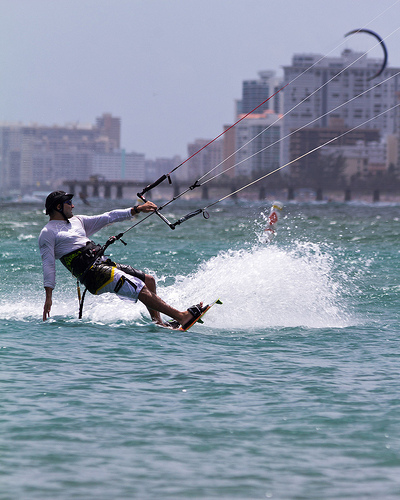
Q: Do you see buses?
A: No, there are no buses.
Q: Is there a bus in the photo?
A: No, there are no buses.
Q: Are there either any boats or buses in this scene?
A: No, there are no buses or boats.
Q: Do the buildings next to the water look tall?
A: Yes, the buildings are tall.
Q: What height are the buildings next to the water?
A: The buildings are tall.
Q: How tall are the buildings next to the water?
A: The buildings are tall.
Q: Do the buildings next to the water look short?
A: No, the buildings are tall.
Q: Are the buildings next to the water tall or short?
A: The buildings are tall.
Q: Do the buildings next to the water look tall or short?
A: The buildings are tall.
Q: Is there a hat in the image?
A: Yes, there is a hat.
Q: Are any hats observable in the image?
A: Yes, there is a hat.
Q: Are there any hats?
A: Yes, there is a hat.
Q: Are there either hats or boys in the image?
A: Yes, there is a hat.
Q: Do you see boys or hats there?
A: Yes, there is a hat.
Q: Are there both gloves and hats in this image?
A: No, there is a hat but no gloves.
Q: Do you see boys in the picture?
A: No, there are no boys.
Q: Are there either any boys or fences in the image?
A: No, there are no boys or fences.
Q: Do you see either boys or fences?
A: No, there are no boys or fences.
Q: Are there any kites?
A: Yes, there is a kite.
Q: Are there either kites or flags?
A: Yes, there is a kite.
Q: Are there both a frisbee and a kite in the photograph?
A: No, there is a kite but no frisbees.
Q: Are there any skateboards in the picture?
A: No, there are no skateboards.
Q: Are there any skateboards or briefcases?
A: No, there are no skateboards or briefcases.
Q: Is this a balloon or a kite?
A: This is a kite.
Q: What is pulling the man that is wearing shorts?
A: The kite is pulling the man.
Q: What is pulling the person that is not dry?
A: The kite is pulling the man.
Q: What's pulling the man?
A: The kite is pulling the man.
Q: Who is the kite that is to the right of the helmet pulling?
A: The kite is pulling the man.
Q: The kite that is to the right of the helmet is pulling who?
A: The kite is pulling the man.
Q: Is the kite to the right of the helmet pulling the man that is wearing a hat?
A: Yes, the kite is pulling the man.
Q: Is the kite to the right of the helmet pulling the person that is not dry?
A: Yes, the kite is pulling the man.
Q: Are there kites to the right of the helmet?
A: Yes, there is a kite to the right of the helmet.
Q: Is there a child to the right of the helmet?
A: No, there is a kite to the right of the helmet.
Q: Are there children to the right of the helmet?
A: No, there is a kite to the right of the helmet.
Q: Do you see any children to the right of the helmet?
A: No, there is a kite to the right of the helmet.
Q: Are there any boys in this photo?
A: No, there are no boys.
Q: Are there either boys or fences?
A: No, there are no boys or fences.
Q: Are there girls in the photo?
A: No, there are no girls.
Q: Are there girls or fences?
A: No, there are no girls or fences.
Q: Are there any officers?
A: No, there are no officers.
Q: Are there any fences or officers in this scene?
A: No, there are no officers or fences.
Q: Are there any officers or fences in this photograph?
A: No, there are no officers or fences.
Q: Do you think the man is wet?
A: Yes, the man is wet.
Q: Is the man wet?
A: Yes, the man is wet.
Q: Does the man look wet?
A: Yes, the man is wet.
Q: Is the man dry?
A: No, the man is wet.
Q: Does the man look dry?
A: No, the man is wet.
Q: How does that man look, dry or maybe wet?
A: The man is wet.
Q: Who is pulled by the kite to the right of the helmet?
A: The man is pulled by the kite.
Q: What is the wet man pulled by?
A: The man is pulled by the kite.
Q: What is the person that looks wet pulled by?
A: The man is pulled by the kite.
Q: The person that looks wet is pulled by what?
A: The man is pulled by the kite.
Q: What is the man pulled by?
A: The man is pulled by the kite.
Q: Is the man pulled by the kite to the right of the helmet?
A: Yes, the man is pulled by the kite.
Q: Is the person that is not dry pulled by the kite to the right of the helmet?
A: Yes, the man is pulled by the kite.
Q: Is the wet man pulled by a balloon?
A: No, the man is pulled by the kite.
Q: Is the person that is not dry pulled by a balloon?
A: No, the man is pulled by the kite.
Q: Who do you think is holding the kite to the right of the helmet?
A: The man is holding the kite.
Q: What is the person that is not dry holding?
A: The man is holding the kite.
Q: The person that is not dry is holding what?
A: The man is holding the kite.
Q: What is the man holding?
A: The man is holding the kite.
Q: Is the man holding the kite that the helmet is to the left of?
A: Yes, the man is holding the kite.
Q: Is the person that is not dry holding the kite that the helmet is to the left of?
A: Yes, the man is holding the kite.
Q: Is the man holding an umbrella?
A: No, the man is holding the kite.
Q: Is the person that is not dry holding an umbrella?
A: No, the man is holding the kite.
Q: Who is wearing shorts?
A: The man is wearing shorts.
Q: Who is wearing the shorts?
A: The man is wearing shorts.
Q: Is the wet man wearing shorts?
A: Yes, the man is wearing shorts.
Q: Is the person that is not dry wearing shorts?
A: Yes, the man is wearing shorts.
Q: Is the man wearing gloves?
A: No, the man is wearing shorts.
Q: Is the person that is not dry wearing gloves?
A: No, the man is wearing shorts.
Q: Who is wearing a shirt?
A: The man is wearing a shirt.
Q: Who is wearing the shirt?
A: The man is wearing a shirt.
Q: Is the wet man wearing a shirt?
A: Yes, the man is wearing a shirt.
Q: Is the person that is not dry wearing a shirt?
A: Yes, the man is wearing a shirt.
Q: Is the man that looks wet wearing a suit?
A: No, the man is wearing a shirt.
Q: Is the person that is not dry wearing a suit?
A: No, the man is wearing a shirt.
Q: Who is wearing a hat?
A: The man is wearing a hat.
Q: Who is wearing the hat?
A: The man is wearing a hat.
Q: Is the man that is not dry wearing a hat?
A: Yes, the man is wearing a hat.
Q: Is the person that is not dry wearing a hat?
A: Yes, the man is wearing a hat.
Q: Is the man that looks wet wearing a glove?
A: No, the man is wearing a hat.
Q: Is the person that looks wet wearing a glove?
A: No, the man is wearing a hat.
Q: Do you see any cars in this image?
A: No, there are no cars.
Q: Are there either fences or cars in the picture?
A: No, there are no cars or fences.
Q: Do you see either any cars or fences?
A: No, there are no cars or fences.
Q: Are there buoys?
A: Yes, there is a buoy.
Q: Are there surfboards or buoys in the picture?
A: Yes, there is a buoy.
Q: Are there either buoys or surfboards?
A: Yes, there is a buoy.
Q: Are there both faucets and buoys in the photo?
A: No, there is a buoy but no faucets.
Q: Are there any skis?
A: No, there are no skis.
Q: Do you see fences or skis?
A: No, there are no skis or fences.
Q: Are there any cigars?
A: No, there are no cigars.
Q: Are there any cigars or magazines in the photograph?
A: No, there are no cigars or magazines.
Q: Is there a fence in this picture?
A: No, there are no fences.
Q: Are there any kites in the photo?
A: Yes, there is a kite.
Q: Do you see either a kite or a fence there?
A: Yes, there is a kite.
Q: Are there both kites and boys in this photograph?
A: No, there is a kite but no boys.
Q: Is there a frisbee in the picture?
A: No, there are no frisbees.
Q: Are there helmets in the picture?
A: Yes, there is a helmet.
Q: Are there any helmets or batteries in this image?
A: Yes, there is a helmet.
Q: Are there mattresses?
A: No, there are no mattresses.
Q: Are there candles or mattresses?
A: No, there are no mattresses or candles.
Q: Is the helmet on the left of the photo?
A: Yes, the helmet is on the left of the image.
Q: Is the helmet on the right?
A: No, the helmet is on the left of the image.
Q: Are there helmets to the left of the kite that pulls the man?
A: Yes, there is a helmet to the left of the kite.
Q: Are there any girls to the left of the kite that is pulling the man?
A: No, there is a helmet to the left of the kite.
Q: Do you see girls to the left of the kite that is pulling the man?
A: No, there is a helmet to the left of the kite.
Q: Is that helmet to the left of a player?
A: No, the helmet is to the left of the kite.